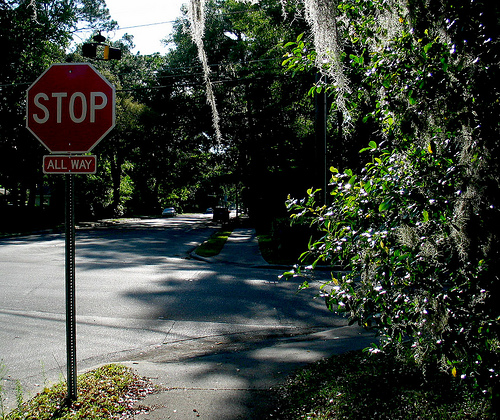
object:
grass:
[11, 363, 134, 419]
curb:
[130, 361, 140, 365]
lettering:
[46, 154, 97, 173]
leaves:
[313, 196, 320, 202]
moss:
[297, 2, 362, 143]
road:
[0, 207, 259, 355]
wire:
[12, 10, 220, 40]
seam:
[150, 383, 289, 394]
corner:
[5, 333, 157, 418]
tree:
[257, 0, 500, 397]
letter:
[51, 88, 67, 129]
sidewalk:
[116, 341, 297, 417]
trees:
[2, 3, 52, 233]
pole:
[63, 169, 77, 401]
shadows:
[109, 264, 329, 331]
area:
[2, 0, 499, 418]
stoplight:
[92, 40, 124, 63]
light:
[101, 43, 124, 61]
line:
[25, 5, 277, 43]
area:
[196, 327, 326, 377]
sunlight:
[135, 261, 170, 281]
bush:
[337, 0, 493, 420]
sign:
[21, 57, 121, 179]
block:
[126, 192, 236, 252]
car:
[160, 206, 177, 218]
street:
[4, 208, 352, 378]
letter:
[31, 93, 57, 127]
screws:
[64, 137, 73, 173]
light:
[26, 14, 199, 35]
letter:
[64, 89, 91, 135]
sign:
[22, 58, 121, 408]